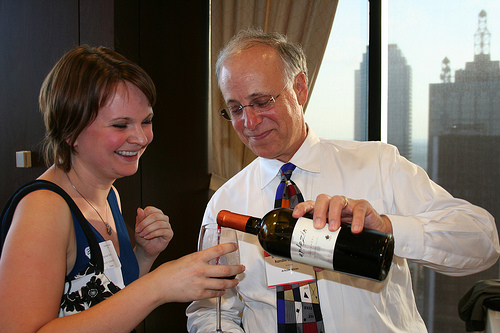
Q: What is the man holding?
A: The bottle.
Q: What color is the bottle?
A: Black.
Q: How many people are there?
A: Two.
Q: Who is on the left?
A: The woman.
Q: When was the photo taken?
A: Day time.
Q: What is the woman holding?
A: The glass.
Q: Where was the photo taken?
A: At a wine tasting.